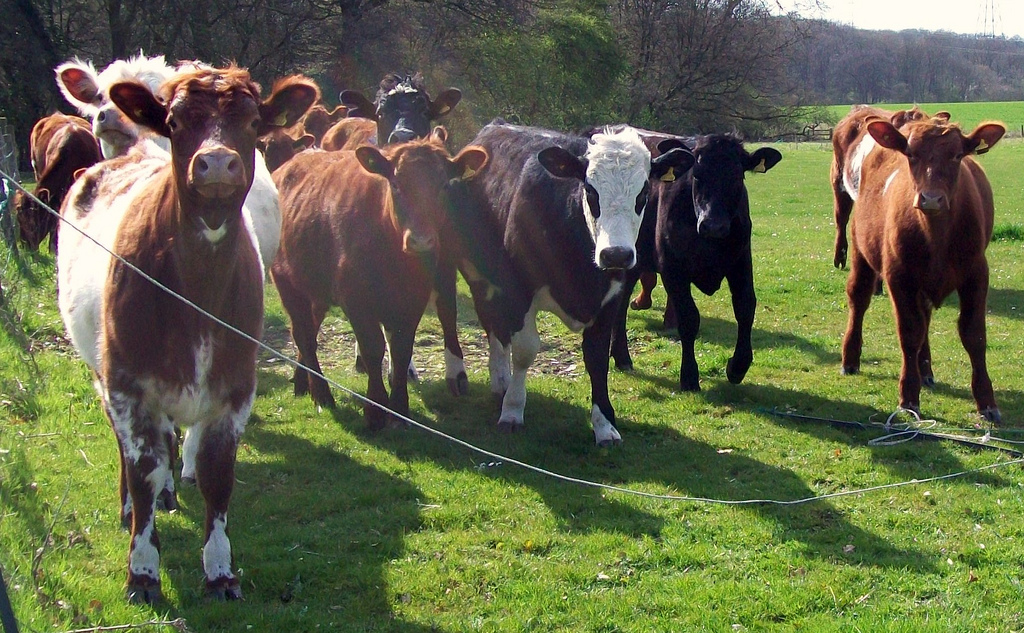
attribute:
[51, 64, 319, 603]
cow — brown, white, adult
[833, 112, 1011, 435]
cow — brown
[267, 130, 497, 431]
cow — dark brown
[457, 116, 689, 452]
cow — adult, white, black